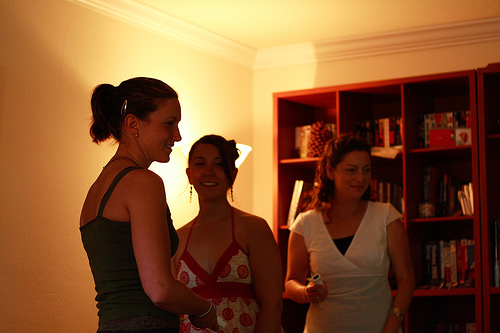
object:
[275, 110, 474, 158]
books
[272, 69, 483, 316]
shelf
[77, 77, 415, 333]
women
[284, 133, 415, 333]
woman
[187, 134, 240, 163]
hair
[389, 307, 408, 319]
bracelet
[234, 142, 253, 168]
lamp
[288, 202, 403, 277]
shirt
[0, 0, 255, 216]
wall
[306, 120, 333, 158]
cone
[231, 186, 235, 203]
earring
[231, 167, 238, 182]
ear